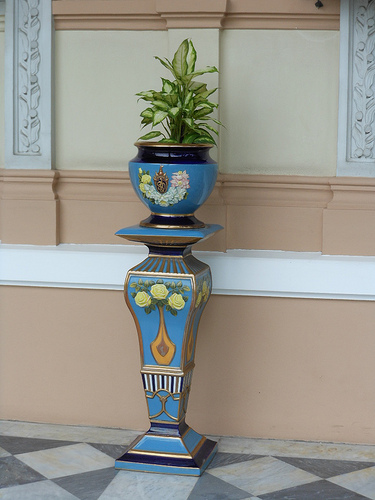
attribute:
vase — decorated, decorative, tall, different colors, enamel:
[108, 34, 241, 249]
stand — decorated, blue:
[97, 225, 246, 479]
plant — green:
[131, 36, 226, 137]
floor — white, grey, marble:
[233, 447, 371, 494]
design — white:
[11, 2, 45, 163]